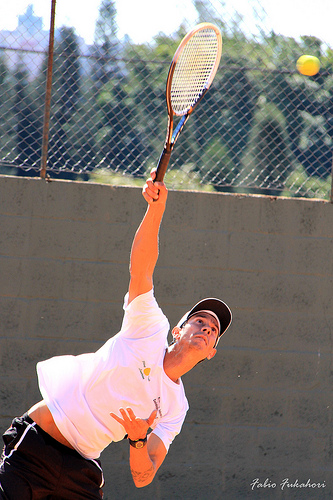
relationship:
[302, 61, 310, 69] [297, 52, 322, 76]
yellow ten ball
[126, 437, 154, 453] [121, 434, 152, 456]
watch on wrist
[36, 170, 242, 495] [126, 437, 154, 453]
man wearing watch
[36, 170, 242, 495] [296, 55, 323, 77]
man playing ball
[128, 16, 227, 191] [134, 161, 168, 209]
racket in hand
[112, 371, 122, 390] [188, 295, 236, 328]
white black cap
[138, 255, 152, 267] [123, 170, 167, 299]
tattoo on arm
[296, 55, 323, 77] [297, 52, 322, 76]
ball player ball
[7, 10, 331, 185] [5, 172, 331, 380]
fence securing court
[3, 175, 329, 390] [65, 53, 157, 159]
wall and wire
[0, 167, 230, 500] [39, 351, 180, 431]
man wearing shirt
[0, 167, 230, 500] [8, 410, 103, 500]
man wearing shorts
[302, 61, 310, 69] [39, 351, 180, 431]
yellow on shirt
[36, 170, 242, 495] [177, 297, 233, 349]
man wearing cap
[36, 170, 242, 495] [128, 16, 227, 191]
man swinging racket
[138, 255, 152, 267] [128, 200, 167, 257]
tattoo on forearm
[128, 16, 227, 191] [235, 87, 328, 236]
racket in air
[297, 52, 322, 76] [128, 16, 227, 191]
ball close racket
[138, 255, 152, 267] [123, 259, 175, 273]
tattoo near elbow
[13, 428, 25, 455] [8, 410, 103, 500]
stripe on shorts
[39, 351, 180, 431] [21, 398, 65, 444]
shirt reveal midriff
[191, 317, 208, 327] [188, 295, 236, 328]
eyes under cap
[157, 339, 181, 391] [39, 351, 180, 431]
neck white shirt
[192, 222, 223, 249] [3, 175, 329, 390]
grey of wall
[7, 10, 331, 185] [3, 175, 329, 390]
fence on wall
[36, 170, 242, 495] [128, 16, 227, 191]
man holding racket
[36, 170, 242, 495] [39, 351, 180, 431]
man wearing shirt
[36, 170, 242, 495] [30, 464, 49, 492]
man wearing black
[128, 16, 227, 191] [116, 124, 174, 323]
racket being swung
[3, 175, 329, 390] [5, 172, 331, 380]
wall at court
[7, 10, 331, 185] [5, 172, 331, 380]
fence surrounding court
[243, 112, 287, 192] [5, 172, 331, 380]
trees beyond court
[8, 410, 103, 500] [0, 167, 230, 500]
shorts on man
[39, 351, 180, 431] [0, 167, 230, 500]
shirt on man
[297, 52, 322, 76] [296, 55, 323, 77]
ball for ball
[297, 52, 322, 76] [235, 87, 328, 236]
ball in air